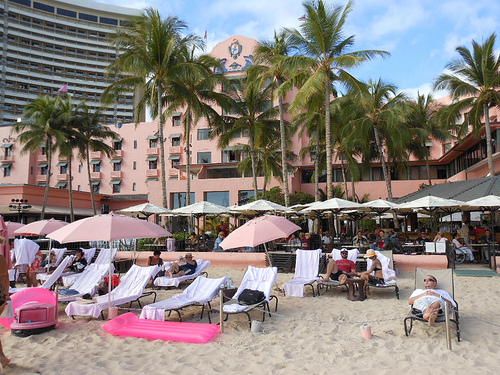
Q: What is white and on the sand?
A: The beach chairs.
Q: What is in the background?
A: The palm trees.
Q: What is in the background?
A: The pink building.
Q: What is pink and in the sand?
A: A flotation device.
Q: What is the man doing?
A: Laying on the beach chair.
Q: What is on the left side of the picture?
A: A tall building.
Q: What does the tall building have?
A: Many glass windows.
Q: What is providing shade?
A: The umbrellas.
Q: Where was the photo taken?
A: At a beach.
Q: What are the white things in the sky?
A: Clouds.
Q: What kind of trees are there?
A: Palm trees.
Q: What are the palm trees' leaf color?
A: Green.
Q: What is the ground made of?
A: Sand.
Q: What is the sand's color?
A: Beige.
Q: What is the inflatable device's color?
A: Pink.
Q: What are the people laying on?
A: Chairs.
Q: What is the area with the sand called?
A: Beach.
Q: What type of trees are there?
A: Palm trees.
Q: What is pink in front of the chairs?
A: Floatable.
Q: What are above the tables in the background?
A: Umbrellas.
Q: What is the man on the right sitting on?
A: Lounge chair.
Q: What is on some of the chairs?
A: Towels.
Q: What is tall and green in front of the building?
A: Trees.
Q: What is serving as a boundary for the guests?
A: Small chain.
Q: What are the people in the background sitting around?
A: Tables.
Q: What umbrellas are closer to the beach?
A: Pink.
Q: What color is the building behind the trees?
A: Pink.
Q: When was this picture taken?
A: Daytime.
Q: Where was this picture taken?
A: The beach.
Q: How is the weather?
A: Clear.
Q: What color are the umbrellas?
A: Pink and white.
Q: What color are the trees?
A: Green.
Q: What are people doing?
A: Sunbathing.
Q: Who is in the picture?
A: Men and women.